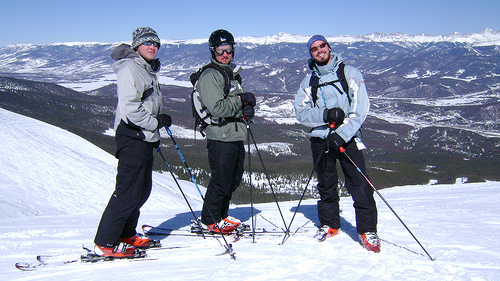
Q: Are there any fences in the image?
A: No, there are no fences.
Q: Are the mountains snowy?
A: Yes, the mountains are snowy.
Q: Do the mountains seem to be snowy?
A: Yes, the mountains are snowy.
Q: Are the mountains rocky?
A: No, the mountains are snowy.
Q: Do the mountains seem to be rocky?
A: No, the mountains are snowy.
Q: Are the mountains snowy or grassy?
A: The mountains are snowy.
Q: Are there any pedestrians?
A: No, there are no pedestrians.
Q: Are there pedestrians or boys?
A: No, there are no pedestrians or boys.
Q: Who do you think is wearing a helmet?
A: The man is wearing a helmet.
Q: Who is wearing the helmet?
A: The man is wearing a helmet.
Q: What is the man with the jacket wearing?
A: The man is wearing a helmet.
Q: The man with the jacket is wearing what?
A: The man is wearing a helmet.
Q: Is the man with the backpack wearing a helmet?
A: Yes, the man is wearing a helmet.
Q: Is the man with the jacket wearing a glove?
A: No, the man is wearing a helmet.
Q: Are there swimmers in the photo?
A: No, there are no swimmers.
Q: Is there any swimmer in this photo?
A: No, there are no swimmers.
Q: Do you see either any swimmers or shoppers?
A: No, there are no swimmers or shoppers.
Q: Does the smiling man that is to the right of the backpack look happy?
A: Yes, the man is happy.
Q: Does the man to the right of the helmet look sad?
A: No, the man is happy.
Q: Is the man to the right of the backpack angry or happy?
A: The man is happy.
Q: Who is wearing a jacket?
A: The man is wearing a jacket.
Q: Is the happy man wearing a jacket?
A: Yes, the man is wearing a jacket.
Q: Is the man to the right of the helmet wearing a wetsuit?
A: No, the man is wearing a jacket.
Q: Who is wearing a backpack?
A: The man is wearing a backpack.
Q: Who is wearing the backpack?
A: The man is wearing a backpack.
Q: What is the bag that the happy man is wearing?
A: The bag is a backpack.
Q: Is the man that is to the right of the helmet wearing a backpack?
A: Yes, the man is wearing a backpack.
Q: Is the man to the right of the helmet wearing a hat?
A: No, the man is wearing a backpack.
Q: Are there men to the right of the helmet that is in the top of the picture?
A: Yes, there is a man to the right of the helmet.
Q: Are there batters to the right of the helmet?
A: No, there is a man to the right of the helmet.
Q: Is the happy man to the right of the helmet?
A: Yes, the man is to the right of the helmet.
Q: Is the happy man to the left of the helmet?
A: No, the man is to the right of the helmet.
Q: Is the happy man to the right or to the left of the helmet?
A: The man is to the right of the helmet.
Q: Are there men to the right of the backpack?
A: Yes, there is a man to the right of the backpack.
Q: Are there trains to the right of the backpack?
A: No, there is a man to the right of the backpack.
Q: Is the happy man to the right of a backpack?
A: Yes, the man is to the right of a backpack.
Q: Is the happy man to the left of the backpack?
A: No, the man is to the right of the backpack.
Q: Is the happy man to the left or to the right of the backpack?
A: The man is to the right of the backpack.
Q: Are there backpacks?
A: Yes, there is a backpack.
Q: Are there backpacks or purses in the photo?
A: Yes, there is a backpack.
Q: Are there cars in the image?
A: No, there are no cars.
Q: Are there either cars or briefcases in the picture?
A: No, there are no cars or briefcases.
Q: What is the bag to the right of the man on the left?
A: The bag is a backpack.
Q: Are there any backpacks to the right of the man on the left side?
A: Yes, there is a backpack to the right of the man.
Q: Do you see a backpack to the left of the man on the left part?
A: No, the backpack is to the right of the man.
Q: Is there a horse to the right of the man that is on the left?
A: No, there is a backpack to the right of the man.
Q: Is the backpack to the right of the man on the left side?
A: Yes, the backpack is to the right of the man.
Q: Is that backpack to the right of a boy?
A: No, the backpack is to the right of the man.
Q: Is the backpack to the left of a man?
A: No, the backpack is to the right of a man.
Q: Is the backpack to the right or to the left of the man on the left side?
A: The backpack is to the right of the man.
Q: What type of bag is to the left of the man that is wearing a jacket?
A: The bag is a backpack.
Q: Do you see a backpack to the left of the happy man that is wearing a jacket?
A: Yes, there is a backpack to the left of the man.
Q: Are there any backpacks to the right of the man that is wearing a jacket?
A: No, the backpack is to the left of the man.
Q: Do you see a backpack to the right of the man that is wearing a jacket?
A: No, the backpack is to the left of the man.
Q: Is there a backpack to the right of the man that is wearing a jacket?
A: No, the backpack is to the left of the man.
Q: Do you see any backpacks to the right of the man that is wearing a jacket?
A: No, the backpack is to the left of the man.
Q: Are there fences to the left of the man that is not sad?
A: No, there is a backpack to the left of the man.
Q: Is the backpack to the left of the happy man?
A: Yes, the backpack is to the left of the man.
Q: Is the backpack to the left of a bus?
A: No, the backpack is to the left of the man.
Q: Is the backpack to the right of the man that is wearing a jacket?
A: No, the backpack is to the left of the man.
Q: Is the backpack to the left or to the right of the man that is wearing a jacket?
A: The backpack is to the left of the man.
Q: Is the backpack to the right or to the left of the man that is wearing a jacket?
A: The backpack is to the left of the man.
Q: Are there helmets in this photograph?
A: Yes, there is a helmet.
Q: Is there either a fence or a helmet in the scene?
A: Yes, there is a helmet.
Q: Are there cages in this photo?
A: No, there are no cages.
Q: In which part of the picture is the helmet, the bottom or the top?
A: The helmet is in the top of the image.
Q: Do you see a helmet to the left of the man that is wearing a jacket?
A: Yes, there is a helmet to the left of the man.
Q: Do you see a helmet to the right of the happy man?
A: No, the helmet is to the left of the man.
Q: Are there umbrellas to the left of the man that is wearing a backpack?
A: No, there is a helmet to the left of the man.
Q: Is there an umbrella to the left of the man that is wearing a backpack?
A: No, there is a helmet to the left of the man.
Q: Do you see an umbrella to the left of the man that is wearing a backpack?
A: No, there is a helmet to the left of the man.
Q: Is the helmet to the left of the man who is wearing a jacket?
A: Yes, the helmet is to the left of the man.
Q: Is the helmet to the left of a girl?
A: No, the helmet is to the left of the man.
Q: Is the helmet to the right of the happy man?
A: No, the helmet is to the left of the man.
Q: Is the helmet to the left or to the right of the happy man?
A: The helmet is to the left of the man.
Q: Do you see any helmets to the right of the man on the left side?
A: Yes, there is a helmet to the right of the man.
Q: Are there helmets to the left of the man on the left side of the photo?
A: No, the helmet is to the right of the man.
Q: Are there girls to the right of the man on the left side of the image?
A: No, there is a helmet to the right of the man.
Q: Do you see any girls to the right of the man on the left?
A: No, there is a helmet to the right of the man.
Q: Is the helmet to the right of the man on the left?
A: Yes, the helmet is to the right of the man.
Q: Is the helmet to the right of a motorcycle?
A: No, the helmet is to the right of the man.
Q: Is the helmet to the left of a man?
A: No, the helmet is to the right of a man.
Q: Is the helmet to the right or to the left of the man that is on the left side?
A: The helmet is to the right of the man.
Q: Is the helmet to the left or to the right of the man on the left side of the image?
A: The helmet is to the right of the man.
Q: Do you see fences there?
A: No, there are no fences.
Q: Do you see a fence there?
A: No, there are no fences.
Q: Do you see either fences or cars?
A: No, there are no fences or cars.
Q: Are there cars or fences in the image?
A: No, there are no fences or cars.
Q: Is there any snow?
A: Yes, there is snow.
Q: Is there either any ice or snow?
A: Yes, there is snow.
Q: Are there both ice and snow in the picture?
A: No, there is snow but no ice.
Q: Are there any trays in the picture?
A: No, there are no trays.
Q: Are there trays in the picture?
A: No, there are no trays.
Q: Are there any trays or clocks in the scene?
A: No, there are no trays or clocks.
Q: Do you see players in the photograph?
A: No, there are no players.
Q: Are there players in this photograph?
A: No, there are no players.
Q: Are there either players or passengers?
A: No, there are no players or passengers.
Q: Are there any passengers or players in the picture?
A: No, there are no players or passengers.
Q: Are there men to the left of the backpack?
A: Yes, there is a man to the left of the backpack.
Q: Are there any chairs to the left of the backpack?
A: No, there is a man to the left of the backpack.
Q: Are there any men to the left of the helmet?
A: Yes, there is a man to the left of the helmet.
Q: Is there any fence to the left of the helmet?
A: No, there is a man to the left of the helmet.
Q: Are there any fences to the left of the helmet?
A: No, there is a man to the left of the helmet.